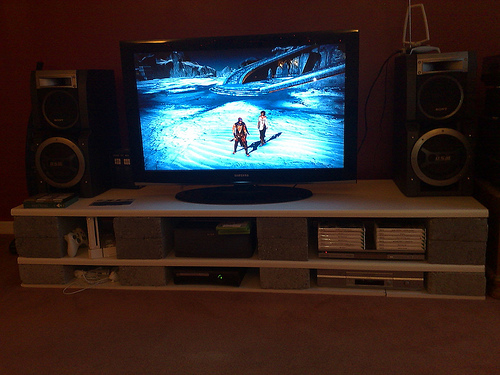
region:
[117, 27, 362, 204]
Television on a stand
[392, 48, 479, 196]
Speaker next to a TV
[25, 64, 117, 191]
Speaker on a stand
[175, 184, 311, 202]
Black TV stand connected to it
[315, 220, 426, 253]
Bunch of DVD's in a case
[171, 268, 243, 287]
Xbox 360 video game console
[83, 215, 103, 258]
White Nintendo video game console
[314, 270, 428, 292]
A DVD player in a cabinet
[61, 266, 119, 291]
Controllers and wires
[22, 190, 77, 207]
A couple of DVD cases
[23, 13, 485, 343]
playing video games in the dark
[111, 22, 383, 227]
flat screen tv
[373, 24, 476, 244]
a black speaker on an entertainment center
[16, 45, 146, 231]
a black speaker next to tv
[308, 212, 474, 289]
video games on a shelf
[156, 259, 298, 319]
a black XBox 360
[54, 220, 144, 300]
A white Xbox 360 controller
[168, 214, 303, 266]
Xbox 360 video games in green cases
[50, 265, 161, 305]
wii nun chucks controller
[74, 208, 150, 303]
a white wii system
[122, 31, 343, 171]
black frame on tv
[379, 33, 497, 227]
black and grey speakers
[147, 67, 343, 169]
ice blue snow on tv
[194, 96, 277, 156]
two characters on game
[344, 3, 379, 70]
brown wall behind tv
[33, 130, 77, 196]
grey frame around subwoofers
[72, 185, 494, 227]
grey desk under tv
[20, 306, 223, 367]
carpet is light brown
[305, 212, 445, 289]
case of DVDs under tv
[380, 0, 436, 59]
white receiver on speakers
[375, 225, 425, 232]
CD on a cubby in a tv stand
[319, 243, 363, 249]
CD on a cubby in a tv stand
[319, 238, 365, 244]
CD on a cubby in a tv stand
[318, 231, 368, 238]
CD on a cubby in a tv stand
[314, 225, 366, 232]
CD on a cubby in a tv stand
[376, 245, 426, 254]
CD on a cubby in a tv stand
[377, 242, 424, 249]
CD on a cubby in a tv stand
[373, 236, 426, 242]
CD on a cubby in a tv stand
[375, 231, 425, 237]
CD on a cubby in a tv stand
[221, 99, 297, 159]
two characters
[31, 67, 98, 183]
a speaker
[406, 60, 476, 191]
the left speaker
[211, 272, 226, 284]
a green button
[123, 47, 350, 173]
a television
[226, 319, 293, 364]
the carpet is brown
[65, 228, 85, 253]
a controller that is white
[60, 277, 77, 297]
a white cord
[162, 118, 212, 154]
snow on the ground